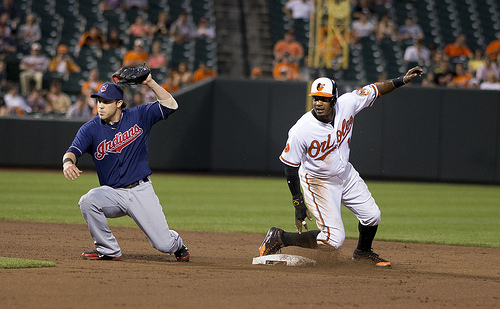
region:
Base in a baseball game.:
[218, 214, 359, 297]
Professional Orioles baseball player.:
[255, 63, 425, 269]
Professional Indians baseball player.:
[59, 61, 192, 261]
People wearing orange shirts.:
[44, 8, 222, 96]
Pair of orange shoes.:
[255, 223, 411, 273]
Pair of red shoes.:
[78, 239, 194, 269]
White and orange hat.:
[308, 75, 343, 105]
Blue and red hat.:
[90, 78, 130, 108]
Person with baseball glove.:
[56, 60, 192, 270]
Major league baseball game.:
[3, 5, 497, 307]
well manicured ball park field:
[182, 182, 277, 217]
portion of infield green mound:
[1, 247, 62, 277]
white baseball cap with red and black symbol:
[304, 69, 344, 101]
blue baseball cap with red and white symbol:
[90, 80, 124, 101]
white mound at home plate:
[245, 246, 325, 271]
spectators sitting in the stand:
[53, 29, 184, 67]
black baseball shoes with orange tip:
[350, 246, 412, 275]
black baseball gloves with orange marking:
[110, 64, 165, 87]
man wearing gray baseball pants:
[70, 180, 195, 261]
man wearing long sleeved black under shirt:
[271, 144, 332, 229]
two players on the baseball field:
[48, 37, 448, 299]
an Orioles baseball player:
[258, 57, 435, 284]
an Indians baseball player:
[53, 61, 223, 275]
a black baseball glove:
[103, 56, 177, 96]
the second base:
[242, 241, 326, 275]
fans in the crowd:
[4, 9, 496, 126]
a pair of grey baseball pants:
[74, 180, 195, 257]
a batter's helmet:
[306, 71, 351, 98]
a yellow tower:
[308, 0, 355, 78]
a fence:
[0, 75, 498, 185]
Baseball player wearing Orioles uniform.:
[265, 63, 423, 270]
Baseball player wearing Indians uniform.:
[55, 57, 201, 214]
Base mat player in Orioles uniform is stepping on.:
[233, 243, 322, 274]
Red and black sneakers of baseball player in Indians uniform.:
[58, 236, 219, 268]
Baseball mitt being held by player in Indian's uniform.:
[101, 63, 170, 90]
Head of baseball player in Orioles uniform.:
[302, 73, 347, 126]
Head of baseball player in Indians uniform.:
[79, 72, 151, 140]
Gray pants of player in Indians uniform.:
[64, 173, 207, 269]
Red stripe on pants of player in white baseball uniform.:
[288, 167, 340, 247]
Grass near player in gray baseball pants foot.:
[1, 249, 64, 274]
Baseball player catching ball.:
[56, 57, 200, 264]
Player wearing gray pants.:
[73, 185, 193, 269]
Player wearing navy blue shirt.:
[65, 98, 182, 188]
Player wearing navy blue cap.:
[88, 74, 129, 109]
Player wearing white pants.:
[295, 167, 398, 253]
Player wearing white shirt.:
[280, 85, 382, 171]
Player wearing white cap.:
[307, 76, 344, 99]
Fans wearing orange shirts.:
[273, 18, 498, 82]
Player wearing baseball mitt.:
[109, 61, 160, 88]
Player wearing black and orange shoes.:
[259, 227, 394, 269]